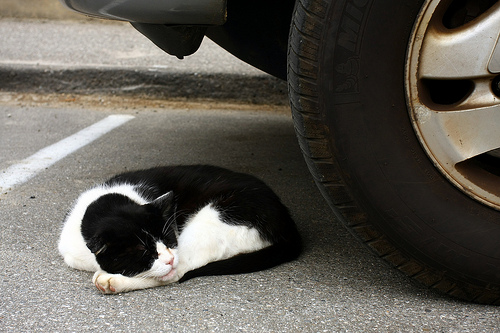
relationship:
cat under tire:
[57, 164, 305, 295] [286, 0, 500, 307]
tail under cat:
[178, 240, 304, 284] [57, 164, 305, 295]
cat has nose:
[57, 164, 305, 295] [167, 256, 174, 266]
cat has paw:
[57, 164, 305, 295] [92, 270, 127, 297]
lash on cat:
[161, 207, 192, 238] [57, 164, 305, 295]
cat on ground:
[57, 164, 305, 295] [0, 18, 500, 331]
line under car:
[0, 113, 137, 197] [61, 1, 500, 305]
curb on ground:
[0, 60, 291, 108] [0, 18, 500, 331]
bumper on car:
[64, 0, 230, 62] [61, 1, 500, 305]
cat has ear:
[57, 164, 305, 295] [143, 190, 180, 231]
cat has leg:
[57, 164, 305, 295] [93, 202, 263, 296]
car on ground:
[61, 1, 500, 305] [0, 18, 500, 331]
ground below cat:
[0, 18, 500, 331] [57, 164, 305, 295]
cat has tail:
[57, 164, 305, 295] [178, 240, 304, 284]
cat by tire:
[57, 164, 305, 295] [286, 0, 500, 307]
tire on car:
[286, 0, 500, 307] [61, 1, 500, 305]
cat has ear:
[57, 164, 305, 295] [85, 226, 123, 254]